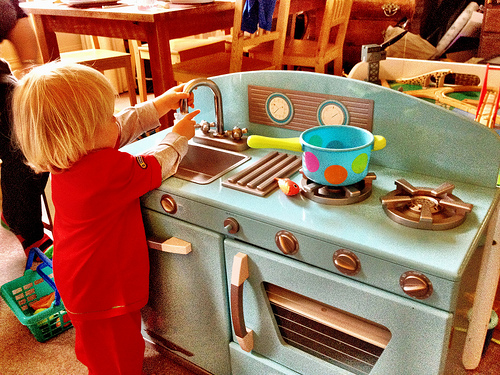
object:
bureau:
[306, 0, 421, 63]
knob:
[162, 198, 174, 211]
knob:
[276, 234, 293, 253]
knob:
[334, 254, 357, 271]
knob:
[403, 276, 428, 297]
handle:
[230, 252, 253, 352]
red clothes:
[51, 148, 162, 374]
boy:
[11, 62, 196, 373]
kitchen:
[112, 70, 500, 375]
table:
[29, 0, 243, 101]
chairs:
[249, 0, 354, 77]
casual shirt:
[54, 100, 186, 321]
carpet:
[0, 226, 192, 375]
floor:
[0, 226, 187, 375]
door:
[223, 237, 451, 375]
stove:
[224, 164, 499, 375]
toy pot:
[247, 124, 386, 186]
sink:
[171, 142, 250, 185]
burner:
[380, 179, 474, 231]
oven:
[222, 237, 453, 375]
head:
[11, 62, 120, 174]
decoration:
[248, 85, 373, 132]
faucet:
[180, 79, 224, 138]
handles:
[381, 2, 400, 17]